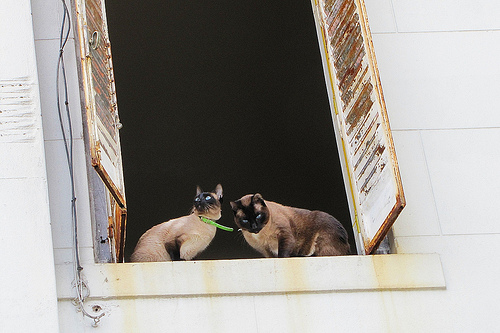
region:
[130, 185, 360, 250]
the cats sit on the window ledge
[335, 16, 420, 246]
The shutter is covered in rust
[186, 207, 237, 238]
The cat is wearing a green collar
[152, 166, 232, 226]
It is looking in the air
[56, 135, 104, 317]
Lines run down the side of the building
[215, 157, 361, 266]
The cat looks down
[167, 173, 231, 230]
Cat has bright blue eyes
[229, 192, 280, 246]
The cat has a dark colored face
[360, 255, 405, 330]
Rust stains running down the window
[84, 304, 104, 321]
A hole in the side of the building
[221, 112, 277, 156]
part of some darkness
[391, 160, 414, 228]
edge of a window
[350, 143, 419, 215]
part of a window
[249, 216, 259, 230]
nose of a cat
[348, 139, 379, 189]
part of a window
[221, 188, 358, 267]
cat on a window sill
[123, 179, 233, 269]
cat on a window sill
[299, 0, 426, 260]
rusty white shutter on a window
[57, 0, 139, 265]
rusty white shutter on a window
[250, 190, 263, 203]
ear of a cat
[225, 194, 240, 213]
ear of a cat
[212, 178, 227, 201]
ear of a cat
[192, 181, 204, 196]
ear of a cat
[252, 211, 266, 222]
blue eye of a cat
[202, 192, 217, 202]
blue eye of a cat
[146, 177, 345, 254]
siamese cats in window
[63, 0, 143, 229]
rusty shutter on window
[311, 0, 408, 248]
rusty shutter on window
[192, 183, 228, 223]
head of siamese cat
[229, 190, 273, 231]
head of siamese cat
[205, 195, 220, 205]
eye of siamese cat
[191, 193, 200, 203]
eye of siamese cat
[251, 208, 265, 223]
eye of siamese cat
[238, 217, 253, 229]
eye of siamese cat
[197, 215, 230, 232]
green collar on cat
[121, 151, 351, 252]
Two cats in the window.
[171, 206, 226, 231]
The cat have on a green collar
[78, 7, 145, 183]
The shutters are rusted.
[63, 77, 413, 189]
Shutters are on the window.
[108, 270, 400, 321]
Rust stain dripping from the window.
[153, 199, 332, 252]
The cats are beige and black.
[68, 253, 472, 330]
The wall has rust stains.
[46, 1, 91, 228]
Wire hanging on the wall.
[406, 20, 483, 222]
The wall is white.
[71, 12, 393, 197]
The window shutters are open.